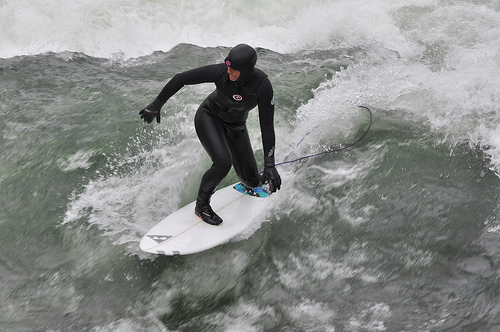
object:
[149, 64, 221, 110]
arm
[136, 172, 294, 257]
board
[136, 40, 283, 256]
surfing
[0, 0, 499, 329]
ocean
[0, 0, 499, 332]
waves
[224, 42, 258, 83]
personhead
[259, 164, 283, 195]
hand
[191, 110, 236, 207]
leg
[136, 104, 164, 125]
hand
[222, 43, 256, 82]
head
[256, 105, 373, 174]
rope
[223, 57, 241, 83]
face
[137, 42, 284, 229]
person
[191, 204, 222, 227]
foot